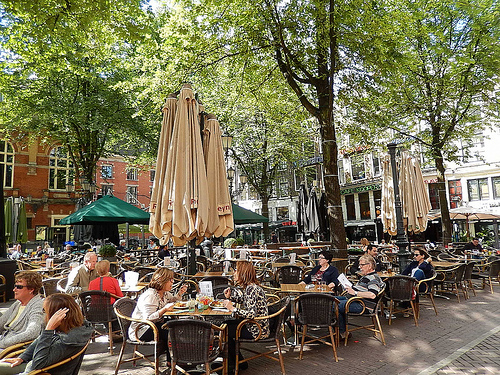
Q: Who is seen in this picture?
A: Men and women.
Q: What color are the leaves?
A: Green.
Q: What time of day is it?
A: Daytime.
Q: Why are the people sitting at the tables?
A: They are eating food.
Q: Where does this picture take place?
A: An outdoor restaurant.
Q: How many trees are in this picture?
A: Four.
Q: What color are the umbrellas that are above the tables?
A: Brown.